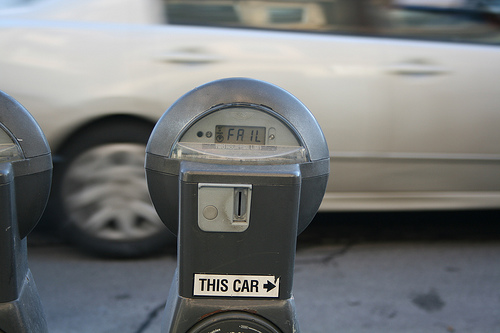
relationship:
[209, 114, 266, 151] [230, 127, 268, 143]
screen says fail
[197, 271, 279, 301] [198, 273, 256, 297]
sticker reads this car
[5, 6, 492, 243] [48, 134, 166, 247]
car has tire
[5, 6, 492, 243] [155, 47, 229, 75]
car has handle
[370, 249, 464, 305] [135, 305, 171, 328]
road has crack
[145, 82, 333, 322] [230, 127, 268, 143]
parking meter says fail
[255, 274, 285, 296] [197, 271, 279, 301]
arrow on sticker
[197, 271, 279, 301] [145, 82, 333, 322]
sticker on parking meter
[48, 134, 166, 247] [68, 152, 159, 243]
tire has rim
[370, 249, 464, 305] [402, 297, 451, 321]
road has spots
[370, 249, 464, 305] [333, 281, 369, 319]
road has spot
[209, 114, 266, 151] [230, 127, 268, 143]
screen reads fail